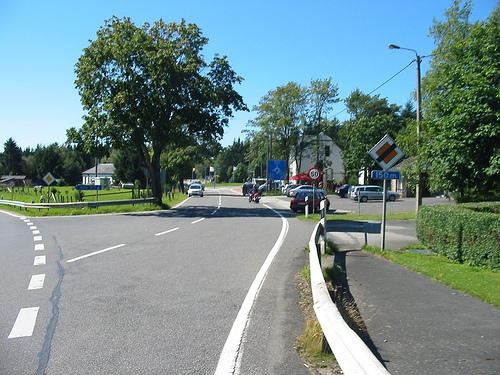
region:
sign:
[370, 133, 404, 167]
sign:
[301, 156, 323, 183]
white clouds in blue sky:
[304, 24, 320, 51]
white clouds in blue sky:
[321, 23, 348, 75]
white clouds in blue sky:
[236, 28, 268, 48]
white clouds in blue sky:
[267, 2, 309, 30]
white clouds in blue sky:
[279, 48, 333, 77]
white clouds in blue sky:
[22, 9, 39, 19]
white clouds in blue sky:
[29, 15, 41, 29]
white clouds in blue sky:
[20, 47, 55, 103]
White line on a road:
[65, 238, 132, 282]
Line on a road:
[63, 234, 138, 268]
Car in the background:
[186, 184, 203, 196]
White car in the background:
[189, 182, 207, 195]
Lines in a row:
[7, 247, 52, 350]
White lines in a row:
[4, 252, 48, 347]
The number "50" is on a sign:
[306, 166, 323, 181]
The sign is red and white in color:
[306, 167, 323, 179]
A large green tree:
[59, 15, 245, 224]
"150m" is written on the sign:
[370, 168, 404, 179]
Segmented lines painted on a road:
[11, 214, 50, 345]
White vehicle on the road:
[187, 185, 204, 197]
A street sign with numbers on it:
[369, 169, 400, 179]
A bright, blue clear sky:
[6, 5, 480, 142]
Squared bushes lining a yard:
[413, 190, 499, 272]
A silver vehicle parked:
[348, 183, 398, 200]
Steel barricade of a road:
[1, 196, 161, 211]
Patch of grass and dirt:
[296, 265, 369, 370]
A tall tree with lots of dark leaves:
[418, 7, 494, 199]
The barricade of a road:
[308, 218, 390, 373]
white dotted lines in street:
[3, 212, 53, 351]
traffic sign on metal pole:
[362, 164, 409, 255]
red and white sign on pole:
[302, 165, 325, 216]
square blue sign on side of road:
[260, 154, 293, 185]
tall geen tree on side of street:
[61, 8, 252, 215]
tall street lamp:
[384, 37, 439, 213]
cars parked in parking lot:
[332, 178, 401, 207]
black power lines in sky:
[329, 53, 431, 130]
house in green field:
[72, 155, 121, 187]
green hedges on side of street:
[412, 189, 499, 271]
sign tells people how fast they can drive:
[306, 165, 321, 183]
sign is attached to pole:
[305, 165, 322, 182]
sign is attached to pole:
[365, 132, 406, 170]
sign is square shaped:
[363, 133, 405, 172]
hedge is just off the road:
[414, 195, 498, 274]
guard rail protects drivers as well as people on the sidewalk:
[307, 215, 388, 374]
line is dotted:
[1, 205, 51, 345]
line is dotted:
[65, 190, 223, 265]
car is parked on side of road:
[187, 185, 204, 198]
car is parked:
[347, 185, 402, 204]